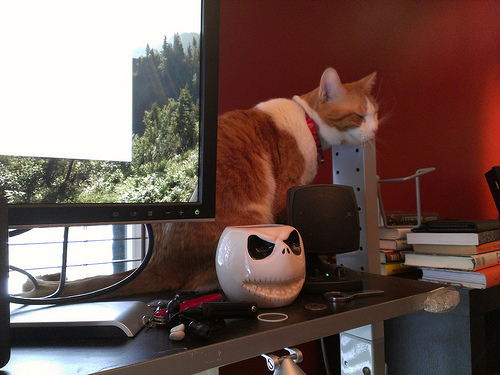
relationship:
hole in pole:
[331, 145, 343, 159] [332, 145, 385, 374]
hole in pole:
[352, 144, 362, 156] [332, 145, 385, 374]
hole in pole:
[352, 164, 361, 176] [332, 145, 385, 374]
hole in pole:
[352, 184, 361, 195] [332, 145, 385, 374]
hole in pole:
[355, 220, 365, 236] [332, 145, 385, 374]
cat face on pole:
[328, 92, 380, 143] [332, 145, 385, 374]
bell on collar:
[316, 156, 326, 165] [291, 99, 326, 158]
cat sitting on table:
[18, 66, 385, 297] [0, 254, 445, 374]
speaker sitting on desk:
[285, 182, 364, 300] [12, 267, 452, 373]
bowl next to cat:
[214, 223, 305, 311] [18, 66, 385, 297]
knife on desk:
[140, 283, 222, 328] [0, 264, 452, 374]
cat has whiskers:
[18, 66, 385, 297] [373, 107, 393, 126]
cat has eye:
[18, 66, 385, 297] [353, 111, 365, 121]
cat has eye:
[18, 66, 385, 297] [372, 106, 380, 115]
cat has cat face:
[18, 66, 385, 297] [328, 92, 380, 143]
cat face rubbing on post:
[328, 92, 380, 143] [334, 130, 382, 276]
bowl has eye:
[214, 223, 305, 311] [282, 226, 302, 256]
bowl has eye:
[214, 223, 305, 311] [245, 233, 276, 260]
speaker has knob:
[285, 182, 364, 300] [343, 207, 353, 217]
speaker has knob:
[285, 182, 364, 300] [348, 225, 358, 237]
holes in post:
[332, 144, 370, 272] [330, 136, 383, 278]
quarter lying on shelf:
[304, 300, 327, 315] [2, 265, 453, 374]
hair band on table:
[256, 307, 287, 322] [223, 260, 455, 349]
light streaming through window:
[17, 232, 119, 278] [8, 226, 154, 294]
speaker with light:
[290, 189, 362, 255] [345, 206, 349, 216]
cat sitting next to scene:
[22, 68, 382, 297] [0, 31, 203, 202]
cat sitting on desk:
[22, 68, 382, 297] [12, 267, 452, 373]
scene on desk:
[0, 31, 203, 202] [12, 267, 452, 373]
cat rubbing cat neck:
[22, 68, 382, 297] [299, 96, 317, 110]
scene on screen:
[128, 45, 190, 188] [3, 21, 198, 206]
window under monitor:
[8, 224, 153, 304] [6, 20, 212, 218]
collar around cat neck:
[303, 109, 319, 140] [299, 96, 317, 110]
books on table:
[410, 219, 496, 288] [372, 280, 497, 373]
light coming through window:
[345, 206, 349, 216] [10, 230, 150, 281]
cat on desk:
[22, 68, 382, 297] [0, 258, 464, 373]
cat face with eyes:
[328, 103, 381, 146] [350, 109, 388, 117]